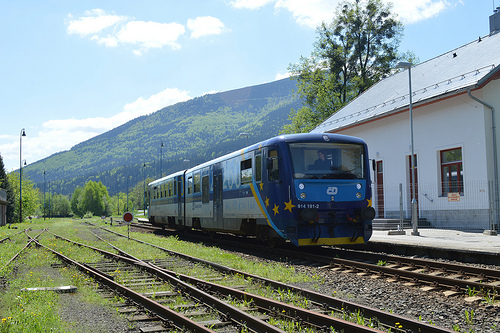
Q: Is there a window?
A: Yes, there is a window.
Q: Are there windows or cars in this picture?
A: Yes, there is a window.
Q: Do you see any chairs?
A: No, there are no chairs.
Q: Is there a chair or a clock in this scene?
A: No, there are no chairs or clocks.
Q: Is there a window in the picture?
A: Yes, there is a window.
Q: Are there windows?
A: Yes, there is a window.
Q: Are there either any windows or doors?
A: Yes, there is a window.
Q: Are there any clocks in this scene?
A: No, there are no clocks.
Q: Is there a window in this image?
A: Yes, there is a window.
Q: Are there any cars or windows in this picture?
A: Yes, there is a window.